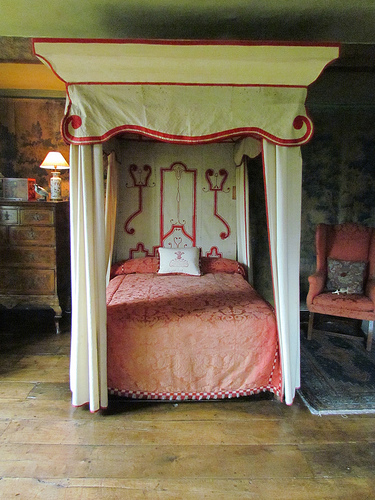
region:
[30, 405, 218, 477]
Brown wood floor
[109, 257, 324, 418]
Red blanket on a bed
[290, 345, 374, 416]
Rug on a wood floor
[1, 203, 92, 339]
Brown wood dresser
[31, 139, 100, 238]
Lamp on a dresser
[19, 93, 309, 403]
White and red canopy over a bed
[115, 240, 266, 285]
Three pillows on a bed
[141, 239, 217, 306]
White and red pillow on a bed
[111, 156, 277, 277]
White and red wall decoration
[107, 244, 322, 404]
Bed made with pillows on it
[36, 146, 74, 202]
an antique ceramic lamp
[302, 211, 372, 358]
A pink Victorian style chair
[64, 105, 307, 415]
An antique four poster bed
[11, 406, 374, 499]
Brown hardwood floors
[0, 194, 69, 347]
an antique, claw foot chest of drawers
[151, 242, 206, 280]
A white, decorative pillow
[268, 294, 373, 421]
A ornamental pattern floor area rug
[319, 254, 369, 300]
A decorative chair pillow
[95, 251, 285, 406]
a pink bedspread with checkered fringe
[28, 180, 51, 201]
a ceramic bird figurine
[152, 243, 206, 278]
a dainty white pillow with red print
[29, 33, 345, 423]
a white and red bed canopy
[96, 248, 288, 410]
a pink patterned blanket on the bed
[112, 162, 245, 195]
gown hooks on the headboard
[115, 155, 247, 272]
squiggly patterns in red on the headboard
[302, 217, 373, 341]
a pink chair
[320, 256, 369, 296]
a grey pillow in the chair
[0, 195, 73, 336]
wooden dresser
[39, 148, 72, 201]
a small lamp is on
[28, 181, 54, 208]
statue of a bird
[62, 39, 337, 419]
there is a white and red canopy over the bed.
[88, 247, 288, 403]
the bedspread is red with a patern on it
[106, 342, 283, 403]
the edging of the bedspread is white and red checkered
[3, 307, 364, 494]
the floor is wood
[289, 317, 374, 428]
there is a carpet under the chair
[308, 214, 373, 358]
a pillow is placed on the chair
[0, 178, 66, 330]
a bureau is beside the bed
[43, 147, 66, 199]
there is a lit lamp on the bureau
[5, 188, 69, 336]
the bureau is made of wood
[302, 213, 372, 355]
an chair with red cloth seating is beside the bed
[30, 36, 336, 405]
red and white bed and canopy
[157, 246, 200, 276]
white pillow with red design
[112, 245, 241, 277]
three pillows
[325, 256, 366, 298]
brown pillow on chair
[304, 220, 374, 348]
chair with pillow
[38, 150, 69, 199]
light colored lamp and shade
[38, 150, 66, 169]
shade of lit up lamp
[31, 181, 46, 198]
bird decoration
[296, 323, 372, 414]
rug with Turkish pattern and white edge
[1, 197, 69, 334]
brown wooden dresser